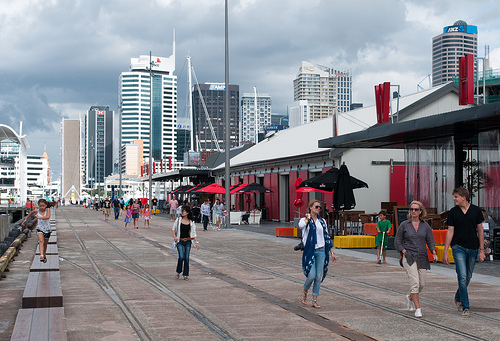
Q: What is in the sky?
A: Clouds.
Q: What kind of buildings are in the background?
A: Skyscrapers.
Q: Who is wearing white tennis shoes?
A: Blond woman with grey shirt.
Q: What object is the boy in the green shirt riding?
A: Scooter.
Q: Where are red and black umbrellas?
A: In front of a restaurant.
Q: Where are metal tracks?
A: On the walkway surface.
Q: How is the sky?
A: Very grey and cloudy.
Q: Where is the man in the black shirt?
A: Next to the woman in the grey shirt.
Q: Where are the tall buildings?
A: In the distant background.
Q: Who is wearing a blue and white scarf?
A: Woman walking with camera on shoulder.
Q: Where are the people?
A: On the street.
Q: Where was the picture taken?
A: In a city.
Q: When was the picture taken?
A: During the daytime.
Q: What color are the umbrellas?
A: Red.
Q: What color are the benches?
A: Brown.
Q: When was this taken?
A: Daytime.